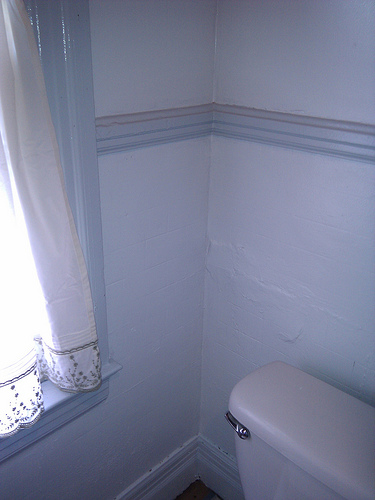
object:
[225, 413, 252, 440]
handle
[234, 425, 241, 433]
chrome plated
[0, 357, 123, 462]
window ledge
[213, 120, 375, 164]
line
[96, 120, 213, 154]
line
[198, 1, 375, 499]
wall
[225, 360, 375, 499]
tank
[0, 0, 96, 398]
window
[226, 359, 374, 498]
top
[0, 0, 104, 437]
curtain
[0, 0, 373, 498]
bathroom